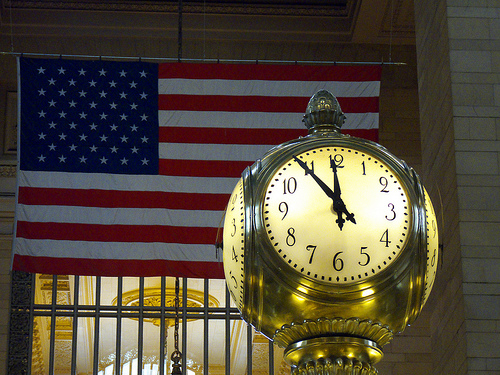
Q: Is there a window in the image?
A: Yes, there is a window.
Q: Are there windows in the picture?
A: Yes, there is a window.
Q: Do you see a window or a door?
A: Yes, there is a window.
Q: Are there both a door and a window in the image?
A: No, there is a window but no doors.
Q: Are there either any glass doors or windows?
A: Yes, there is a glass window.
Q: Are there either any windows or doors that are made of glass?
A: Yes, the window is made of glass.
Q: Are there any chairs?
A: No, there are no chairs.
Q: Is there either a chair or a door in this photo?
A: No, there are no chairs or doors.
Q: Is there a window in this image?
A: Yes, there is a window.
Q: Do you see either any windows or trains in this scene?
A: Yes, there is a window.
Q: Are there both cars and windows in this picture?
A: No, there is a window but no cars.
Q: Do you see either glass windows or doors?
A: Yes, there is a glass window.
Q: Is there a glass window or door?
A: Yes, there is a glass window.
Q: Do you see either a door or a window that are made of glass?
A: Yes, the window is made of glass.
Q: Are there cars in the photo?
A: No, there are no cars.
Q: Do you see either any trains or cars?
A: No, there are no cars or trains.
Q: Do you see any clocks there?
A: Yes, there is a clock.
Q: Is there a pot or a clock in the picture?
A: Yes, there is a clock.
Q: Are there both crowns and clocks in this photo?
A: No, there is a clock but no crowns.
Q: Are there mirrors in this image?
A: No, there are no mirrors.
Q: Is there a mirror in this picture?
A: No, there are no mirrors.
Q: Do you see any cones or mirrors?
A: No, there are no mirrors or cones.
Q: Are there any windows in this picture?
A: Yes, there is a window.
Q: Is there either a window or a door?
A: Yes, there is a window.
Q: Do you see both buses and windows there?
A: No, there is a window but no buses.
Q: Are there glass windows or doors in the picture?
A: Yes, there is a glass window.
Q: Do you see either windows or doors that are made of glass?
A: Yes, the window is made of glass.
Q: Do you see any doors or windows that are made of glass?
A: Yes, the window is made of glass.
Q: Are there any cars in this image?
A: No, there are no cars.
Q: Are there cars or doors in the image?
A: No, there are no cars or doors.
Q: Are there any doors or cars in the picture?
A: No, there are no cars or doors.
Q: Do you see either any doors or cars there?
A: No, there are no cars or doors.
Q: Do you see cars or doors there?
A: No, there are no cars or doors.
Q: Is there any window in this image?
A: Yes, there is a window.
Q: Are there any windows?
A: Yes, there is a window.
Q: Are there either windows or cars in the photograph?
A: Yes, there is a window.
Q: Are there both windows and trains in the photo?
A: No, there is a window but no trains.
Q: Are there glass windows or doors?
A: Yes, there is a glass window.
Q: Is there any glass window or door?
A: Yes, there is a glass window.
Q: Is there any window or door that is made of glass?
A: Yes, the window is made of glass.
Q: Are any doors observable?
A: No, there are no doors.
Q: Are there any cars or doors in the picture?
A: No, there are no doors or cars.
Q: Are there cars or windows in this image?
A: Yes, there is a window.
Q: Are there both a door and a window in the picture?
A: No, there is a window but no doors.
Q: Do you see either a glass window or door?
A: Yes, there is a glass window.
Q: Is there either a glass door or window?
A: Yes, there is a glass window.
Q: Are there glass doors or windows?
A: Yes, there is a glass window.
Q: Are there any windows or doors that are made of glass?
A: Yes, the window is made of glass.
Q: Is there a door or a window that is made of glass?
A: Yes, the window is made of glass.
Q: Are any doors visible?
A: No, there are no doors.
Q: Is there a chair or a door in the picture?
A: No, there are no doors or chairs.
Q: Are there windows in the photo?
A: Yes, there is a window.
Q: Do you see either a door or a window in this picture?
A: Yes, there is a window.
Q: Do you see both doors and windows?
A: No, there is a window but no doors.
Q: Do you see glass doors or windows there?
A: Yes, there is a glass window.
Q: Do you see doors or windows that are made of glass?
A: Yes, the window is made of glass.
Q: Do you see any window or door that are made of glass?
A: Yes, the window is made of glass.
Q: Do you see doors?
A: No, there are no doors.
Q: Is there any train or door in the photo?
A: No, there are no doors or trains.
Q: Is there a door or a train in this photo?
A: No, there are no doors or trains.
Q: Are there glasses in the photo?
A: No, there are no glasses.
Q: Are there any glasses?
A: No, there are no glasses.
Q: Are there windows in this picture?
A: Yes, there is a window.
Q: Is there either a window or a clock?
A: Yes, there is a window.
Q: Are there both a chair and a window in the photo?
A: No, there is a window but no chairs.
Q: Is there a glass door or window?
A: Yes, there is a glass window.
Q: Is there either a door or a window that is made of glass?
A: Yes, the window is made of glass.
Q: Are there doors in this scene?
A: No, there are no doors.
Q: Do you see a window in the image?
A: Yes, there is a window.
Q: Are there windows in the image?
A: Yes, there is a window.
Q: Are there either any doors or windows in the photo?
A: Yes, there is a window.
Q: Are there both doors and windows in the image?
A: No, there is a window but no doors.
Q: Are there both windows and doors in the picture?
A: No, there is a window but no doors.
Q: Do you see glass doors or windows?
A: Yes, there is a glass window.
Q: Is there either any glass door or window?
A: Yes, there is a glass window.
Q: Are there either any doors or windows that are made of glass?
A: Yes, the window is made of glass.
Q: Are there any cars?
A: No, there are no cars.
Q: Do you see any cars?
A: No, there are no cars.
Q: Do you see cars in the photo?
A: No, there are no cars.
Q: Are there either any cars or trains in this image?
A: No, there are no cars or trains.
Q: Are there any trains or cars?
A: No, there are no cars or trains.